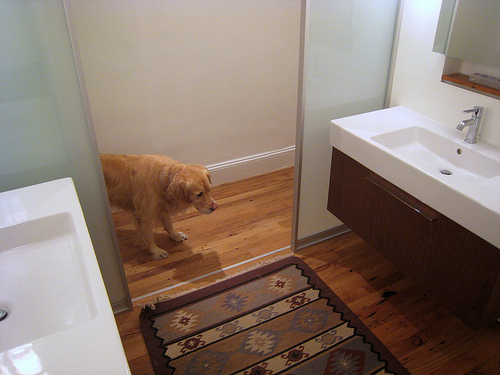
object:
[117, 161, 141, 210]
jersey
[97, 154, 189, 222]
body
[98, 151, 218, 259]
dog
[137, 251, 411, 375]
rug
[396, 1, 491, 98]
vanity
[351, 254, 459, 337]
floor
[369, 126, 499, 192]
sink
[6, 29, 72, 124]
doori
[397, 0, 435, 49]
light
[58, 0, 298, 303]
door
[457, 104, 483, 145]
faucet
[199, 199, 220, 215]
nose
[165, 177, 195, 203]
ear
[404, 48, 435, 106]
wall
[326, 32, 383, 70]
glass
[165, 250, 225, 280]
shadow